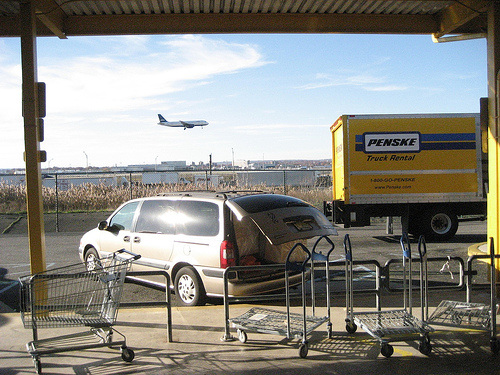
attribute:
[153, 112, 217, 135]
airplane — flight, passenger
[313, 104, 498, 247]
truck — yellow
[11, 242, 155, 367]
cart — silver, shopping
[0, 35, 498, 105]
sky — blue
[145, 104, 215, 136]
jet — white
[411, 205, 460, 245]
wheels — white, black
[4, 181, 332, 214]
grass — tall, brown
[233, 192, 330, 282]
trunk — open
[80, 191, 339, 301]
car — grey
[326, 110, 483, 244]
lorry — yellow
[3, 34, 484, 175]
sky — blue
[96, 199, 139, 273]
door — closed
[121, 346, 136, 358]
wheel — black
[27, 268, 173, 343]
handle — gray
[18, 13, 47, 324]
post — large, yellow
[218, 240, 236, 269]
light — red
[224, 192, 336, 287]
door — open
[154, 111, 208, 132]
plane — large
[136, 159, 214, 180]
building — long, flat, white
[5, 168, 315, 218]
fence — long, clear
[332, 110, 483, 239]
truck — large, blue, yellow